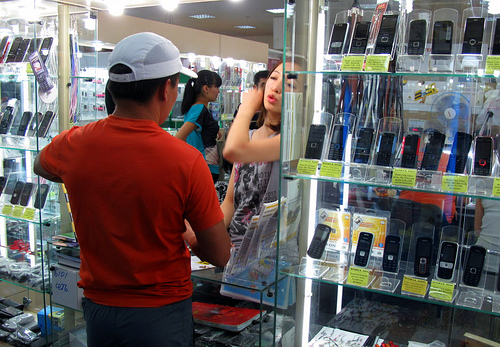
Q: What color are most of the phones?
A: Black.